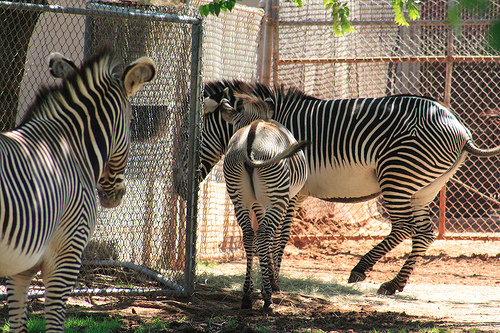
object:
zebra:
[0, 52, 159, 333]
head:
[46, 52, 158, 209]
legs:
[344, 158, 417, 285]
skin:
[317, 109, 388, 150]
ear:
[123, 56, 159, 97]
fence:
[274, 0, 499, 242]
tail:
[462, 137, 499, 159]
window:
[130, 103, 169, 145]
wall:
[17, 0, 263, 267]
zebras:
[217, 98, 314, 315]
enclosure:
[0, 1, 395, 269]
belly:
[312, 169, 373, 204]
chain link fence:
[173, 15, 198, 199]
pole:
[436, 0, 454, 233]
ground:
[0, 245, 498, 333]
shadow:
[269, 300, 499, 332]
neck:
[230, 81, 301, 125]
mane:
[15, 50, 118, 127]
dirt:
[73, 297, 452, 333]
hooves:
[374, 279, 402, 296]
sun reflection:
[281, 32, 320, 55]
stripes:
[64, 109, 103, 165]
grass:
[77, 311, 123, 332]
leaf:
[389, 0, 411, 30]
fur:
[353, 104, 381, 129]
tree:
[0, 0, 50, 132]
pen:
[0, 0, 202, 298]